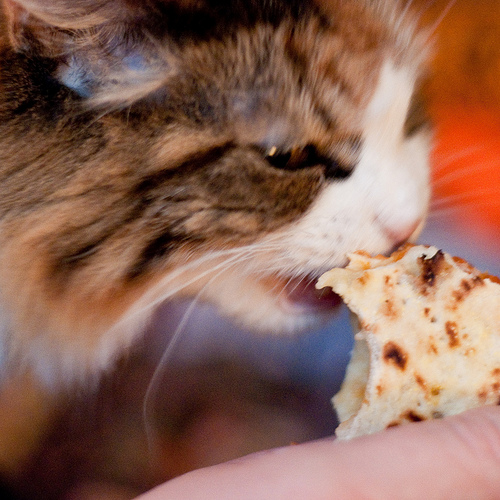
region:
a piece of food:
[307, 243, 494, 448]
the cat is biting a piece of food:
[0, 3, 440, 428]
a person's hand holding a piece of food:
[139, 393, 496, 495]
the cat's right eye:
[224, 131, 345, 188]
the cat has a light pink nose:
[372, 214, 428, 246]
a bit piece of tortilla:
[319, 238, 497, 445]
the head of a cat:
[2, 1, 439, 403]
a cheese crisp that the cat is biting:
[304, 238, 499, 445]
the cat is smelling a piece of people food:
[1, 7, 496, 457]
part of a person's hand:
[139, 399, 496, 498]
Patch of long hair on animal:
[8, 251, 45, 308]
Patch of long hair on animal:
[55, 242, 118, 307]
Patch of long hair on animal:
[7, 320, 104, 397]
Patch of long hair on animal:
[85, 310, 152, 375]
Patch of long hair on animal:
[101, 226, 156, 283]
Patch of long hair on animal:
[130, 187, 209, 235]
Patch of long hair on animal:
[60, 130, 144, 222]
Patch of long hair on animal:
[1, 75, 60, 152]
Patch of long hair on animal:
[7, 138, 88, 208]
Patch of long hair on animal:
[10, 190, 125, 291]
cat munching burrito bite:
[0, 0, 499, 482]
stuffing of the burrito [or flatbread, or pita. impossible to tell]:
[337, 231, 499, 305]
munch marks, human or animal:
[299, 264, 388, 453]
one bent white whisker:
[123, 246, 253, 469]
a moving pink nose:
[366, 214, 430, 250]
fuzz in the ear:
[0, 0, 200, 115]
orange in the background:
[424, 0, 499, 253]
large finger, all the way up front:
[136, 384, 499, 497]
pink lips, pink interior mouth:
[257, 273, 340, 313]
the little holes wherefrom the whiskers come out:
[282, 209, 374, 270]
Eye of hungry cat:
[247, 130, 338, 173]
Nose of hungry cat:
[375, 212, 421, 242]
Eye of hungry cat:
[394, 80, 439, 144]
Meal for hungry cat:
[364, 279, 441, 342]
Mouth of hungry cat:
[235, 268, 325, 316]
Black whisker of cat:
[35, 175, 178, 237]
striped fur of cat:
[218, 62, 316, 109]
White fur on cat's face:
[375, 113, 390, 165]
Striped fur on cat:
[37, 264, 102, 317]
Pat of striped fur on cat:
[351, 13, 387, 73]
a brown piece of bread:
[322, 237, 499, 431]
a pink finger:
[114, 414, 499, 498]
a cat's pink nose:
[375, 210, 417, 245]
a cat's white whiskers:
[121, 245, 327, 429]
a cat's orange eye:
[247, 134, 344, 179]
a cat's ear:
[0, 0, 186, 109]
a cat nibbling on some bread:
[0, 0, 440, 432]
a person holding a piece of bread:
[128, 240, 498, 499]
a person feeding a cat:
[0, 3, 497, 498]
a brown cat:
[0, 5, 425, 294]